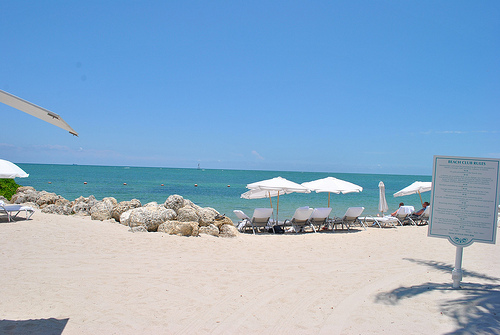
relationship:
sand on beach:
[3, 200, 496, 334] [0, 204, 495, 334]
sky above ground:
[0, 1, 496, 176] [0, 203, 499, 333]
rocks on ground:
[11, 178, 235, 247] [0, 203, 499, 333]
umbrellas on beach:
[237, 165, 437, 211] [0, 204, 495, 334]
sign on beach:
[411, 148, 497, 261] [0, 204, 495, 334]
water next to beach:
[14, 156, 432, 233] [0, 204, 495, 334]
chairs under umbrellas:
[231, 205, 433, 240] [237, 165, 437, 211]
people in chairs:
[387, 197, 430, 223] [231, 205, 433, 240]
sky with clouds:
[0, 1, 496, 176] [125, 42, 165, 72]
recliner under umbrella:
[240, 206, 269, 238] [252, 172, 305, 199]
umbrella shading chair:
[252, 172, 305, 199] [278, 206, 310, 234]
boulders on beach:
[17, 184, 239, 248] [0, 204, 495, 334]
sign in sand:
[411, 148, 497, 261] [3, 200, 496, 334]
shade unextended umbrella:
[240, 224, 359, 239] [252, 172, 305, 199]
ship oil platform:
[195, 160, 206, 172] [68, 162, 83, 167]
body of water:
[18, 157, 443, 221] [14, 156, 432, 233]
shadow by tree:
[374, 249, 493, 335] [2, 178, 22, 203]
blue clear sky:
[1, 1, 497, 127] [0, 1, 496, 176]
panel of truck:
[3, 89, 79, 136] [0, 84, 78, 134]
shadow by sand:
[374, 249, 493, 335] [3, 200, 496, 334]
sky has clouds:
[0, 1, 496, 176] [125, 42, 165, 72]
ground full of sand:
[0, 203, 492, 334] [3, 200, 496, 334]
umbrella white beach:
[252, 172, 305, 199] [0, 204, 495, 334]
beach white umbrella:
[0, 204, 495, 334] [252, 172, 305, 199]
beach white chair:
[0, 204, 495, 334] [278, 206, 310, 234]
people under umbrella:
[387, 197, 430, 223] [252, 172, 305, 199]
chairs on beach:
[231, 205, 433, 240] [0, 204, 495, 334]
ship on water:
[195, 163, 203, 170] [14, 156, 432, 233]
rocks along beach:
[11, 178, 235, 247] [0, 204, 495, 334]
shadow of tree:
[374, 249, 493, 335] [2, 178, 22, 203]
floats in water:
[37, 174, 233, 198] [14, 156, 432, 233]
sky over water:
[0, 1, 496, 176] [14, 156, 432, 233]